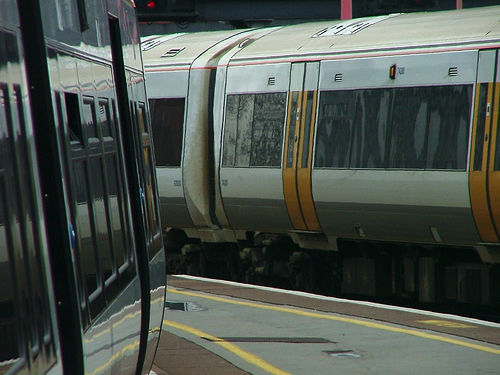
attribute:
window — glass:
[355, 85, 412, 147]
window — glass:
[373, 99, 455, 220]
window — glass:
[314, 50, 377, 170]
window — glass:
[226, 99, 284, 166]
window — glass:
[156, 105, 184, 224]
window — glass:
[104, 69, 169, 206]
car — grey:
[364, 142, 394, 173]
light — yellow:
[384, 60, 399, 86]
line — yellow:
[165, 283, 484, 353]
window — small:
[62, 88, 88, 148]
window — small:
[77, 96, 99, 141]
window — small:
[95, 95, 114, 138]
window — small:
[134, 100, 149, 140]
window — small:
[313, 87, 356, 174]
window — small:
[351, 87, 388, 167]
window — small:
[383, 80, 429, 175]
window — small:
[423, 82, 471, 170]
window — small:
[251, 90, 284, 169]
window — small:
[221, 90, 250, 164]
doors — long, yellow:
[281, 53, 320, 233]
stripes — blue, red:
[227, 32, 484, 63]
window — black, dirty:
[222, 95, 286, 169]